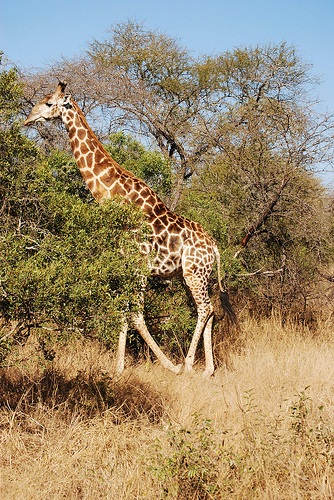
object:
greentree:
[0, 67, 142, 375]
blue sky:
[1, 0, 333, 179]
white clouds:
[154, 3, 195, 27]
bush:
[0, 158, 167, 364]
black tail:
[217, 289, 241, 332]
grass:
[0, 282, 333, 495]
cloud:
[0, 1, 334, 70]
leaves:
[85, 274, 88, 282]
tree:
[0, 51, 334, 370]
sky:
[0, 6, 334, 46]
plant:
[162, 384, 334, 497]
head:
[18, 78, 73, 129]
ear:
[60, 93, 73, 105]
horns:
[54, 77, 74, 93]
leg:
[183, 276, 208, 375]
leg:
[202, 311, 214, 376]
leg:
[133, 281, 180, 378]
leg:
[113, 316, 128, 372]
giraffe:
[18, 75, 232, 382]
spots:
[134, 199, 154, 214]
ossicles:
[54, 76, 69, 102]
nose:
[13, 104, 43, 126]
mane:
[71, 104, 146, 192]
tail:
[211, 238, 223, 296]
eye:
[45, 100, 54, 106]